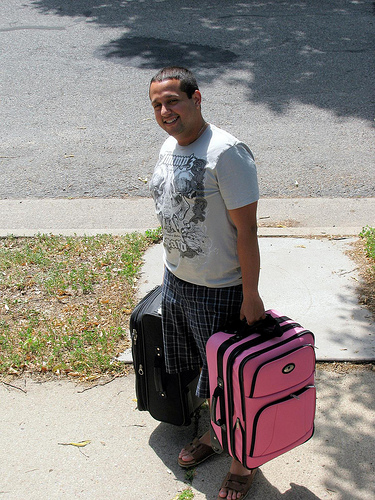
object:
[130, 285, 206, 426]
suitcase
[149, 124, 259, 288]
shirt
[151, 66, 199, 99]
dark hair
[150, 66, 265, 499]
guy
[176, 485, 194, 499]
grass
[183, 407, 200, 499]
crack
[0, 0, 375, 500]
sidewalk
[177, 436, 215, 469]
sandal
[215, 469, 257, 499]
sandal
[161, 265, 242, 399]
plaid shorts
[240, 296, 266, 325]
hand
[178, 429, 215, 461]
feet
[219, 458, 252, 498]
feet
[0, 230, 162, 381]
concrete slab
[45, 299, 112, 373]
grass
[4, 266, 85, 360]
dirt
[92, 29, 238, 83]
black patch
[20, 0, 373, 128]
shadow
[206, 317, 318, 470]
suitcase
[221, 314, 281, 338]
handle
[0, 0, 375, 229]
asphalt